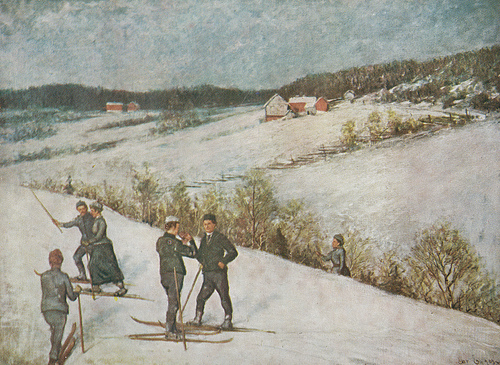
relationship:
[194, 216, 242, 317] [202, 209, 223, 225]
man wearing cap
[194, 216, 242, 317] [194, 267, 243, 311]
man wears pants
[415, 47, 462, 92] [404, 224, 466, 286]
mountain has trees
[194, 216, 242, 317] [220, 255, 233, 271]
man has hands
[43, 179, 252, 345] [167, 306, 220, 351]
people on skiis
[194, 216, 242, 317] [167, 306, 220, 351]
man on skiis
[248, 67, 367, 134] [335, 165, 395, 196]
farm in snow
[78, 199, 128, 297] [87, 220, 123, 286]
people wearing clothes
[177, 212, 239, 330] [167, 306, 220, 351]
man on skiis